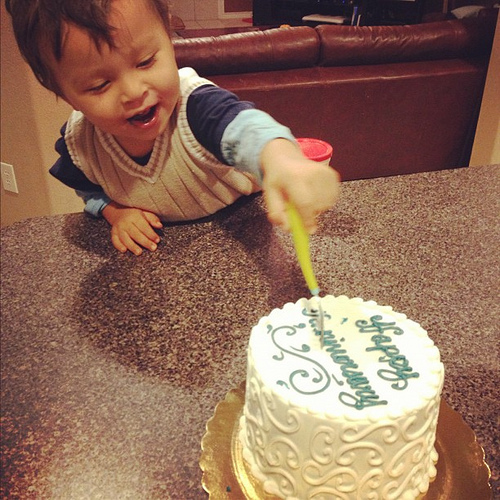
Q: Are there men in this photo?
A: No, there are no men.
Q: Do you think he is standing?
A: Yes, the boy is standing.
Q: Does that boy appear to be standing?
A: Yes, the boy is standing.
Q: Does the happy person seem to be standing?
A: Yes, the boy is standing.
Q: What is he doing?
A: The boy is standing.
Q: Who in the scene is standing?
A: The boy is standing.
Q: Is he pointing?
A: No, the boy is standing.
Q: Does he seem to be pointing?
A: No, the boy is standing.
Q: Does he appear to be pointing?
A: No, the boy is standing.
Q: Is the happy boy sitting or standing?
A: The boy is standing.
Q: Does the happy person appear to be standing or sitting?
A: The boy is standing.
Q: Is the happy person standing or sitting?
A: The boy is standing.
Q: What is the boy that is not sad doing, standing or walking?
A: The boy is standing.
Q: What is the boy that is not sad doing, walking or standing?
A: The boy is standing.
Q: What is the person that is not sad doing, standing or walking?
A: The boy is standing.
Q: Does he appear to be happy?
A: Yes, the boy is happy.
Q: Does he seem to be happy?
A: Yes, the boy is happy.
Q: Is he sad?
A: No, the boy is happy.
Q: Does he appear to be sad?
A: No, the boy is happy.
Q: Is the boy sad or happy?
A: The boy is happy.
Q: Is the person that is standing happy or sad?
A: The boy is happy.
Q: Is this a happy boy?
A: Yes, this is a happy boy.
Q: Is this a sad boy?
A: No, this is a happy boy.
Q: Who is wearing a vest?
A: The boy is wearing a vest.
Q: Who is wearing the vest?
A: The boy is wearing a vest.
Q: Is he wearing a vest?
A: Yes, the boy is wearing a vest.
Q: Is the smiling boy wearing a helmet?
A: No, the boy is wearing a vest.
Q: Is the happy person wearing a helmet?
A: No, the boy is wearing a vest.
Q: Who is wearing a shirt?
A: The boy is wearing a shirt.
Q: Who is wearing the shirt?
A: The boy is wearing a shirt.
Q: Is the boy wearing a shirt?
A: Yes, the boy is wearing a shirt.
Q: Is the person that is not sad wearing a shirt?
A: Yes, the boy is wearing a shirt.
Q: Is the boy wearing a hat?
A: No, the boy is wearing a shirt.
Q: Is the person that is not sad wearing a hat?
A: No, the boy is wearing a shirt.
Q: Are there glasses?
A: No, there are no glasses.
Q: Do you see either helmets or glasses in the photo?
A: No, there are no glasses or helmets.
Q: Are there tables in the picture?
A: Yes, there is a table.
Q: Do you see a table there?
A: Yes, there is a table.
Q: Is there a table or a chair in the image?
A: Yes, there is a table.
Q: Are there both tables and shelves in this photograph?
A: No, there is a table but no shelves.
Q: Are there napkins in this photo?
A: No, there are no napkins.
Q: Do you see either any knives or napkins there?
A: No, there are no napkins or knives.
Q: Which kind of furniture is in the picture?
A: The furniture is a table.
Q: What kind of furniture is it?
A: The piece of furniture is a table.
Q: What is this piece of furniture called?
A: This is a table.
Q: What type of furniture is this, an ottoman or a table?
A: This is a table.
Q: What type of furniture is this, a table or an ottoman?
A: This is a table.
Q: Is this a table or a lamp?
A: This is a table.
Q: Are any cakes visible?
A: Yes, there is a cake.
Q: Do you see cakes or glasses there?
A: Yes, there is a cake.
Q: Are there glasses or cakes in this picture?
A: Yes, there is a cake.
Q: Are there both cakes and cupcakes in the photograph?
A: No, there is a cake but no cupcakes.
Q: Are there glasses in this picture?
A: No, there are no glasses.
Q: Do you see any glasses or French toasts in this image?
A: No, there are no glasses or French toasts.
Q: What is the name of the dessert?
A: The dessert is a cake.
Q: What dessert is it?
A: The dessert is a cake.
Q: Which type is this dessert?
A: This is a cake.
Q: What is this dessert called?
A: This is a cake.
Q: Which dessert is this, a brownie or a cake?
A: This is a cake.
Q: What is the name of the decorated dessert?
A: The dessert is a cake.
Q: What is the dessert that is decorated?
A: The dessert is a cake.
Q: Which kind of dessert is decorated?
A: The dessert is a cake.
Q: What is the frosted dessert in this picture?
A: The dessert is a cake.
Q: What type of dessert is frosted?
A: The dessert is a cake.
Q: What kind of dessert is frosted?
A: The dessert is a cake.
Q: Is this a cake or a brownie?
A: This is a cake.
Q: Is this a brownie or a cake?
A: This is a cake.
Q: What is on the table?
A: The cake is on the table.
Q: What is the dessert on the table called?
A: The dessert is a cake.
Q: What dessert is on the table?
A: The dessert is a cake.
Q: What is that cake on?
A: The cake is on the table.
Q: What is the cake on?
A: The cake is on the table.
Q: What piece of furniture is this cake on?
A: The cake is on the table.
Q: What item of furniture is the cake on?
A: The cake is on the table.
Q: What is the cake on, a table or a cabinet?
A: The cake is on a table.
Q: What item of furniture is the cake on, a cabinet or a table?
A: The cake is on a table.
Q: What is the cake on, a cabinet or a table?
A: The cake is on a table.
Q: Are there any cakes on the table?
A: Yes, there is a cake on the table.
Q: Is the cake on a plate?
A: No, the cake is on the table.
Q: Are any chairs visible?
A: No, there are no chairs.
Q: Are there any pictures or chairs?
A: No, there are no chairs or pictures.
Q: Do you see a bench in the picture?
A: No, there are no benches.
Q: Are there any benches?
A: No, there are no benches.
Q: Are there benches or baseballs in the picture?
A: No, there are no benches or baseballs.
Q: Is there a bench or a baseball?
A: No, there are no benches or baseballs.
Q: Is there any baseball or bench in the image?
A: No, there are no benches or baseballs.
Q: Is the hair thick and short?
A: No, the hair is short but thin.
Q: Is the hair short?
A: Yes, the hair is short.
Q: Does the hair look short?
A: Yes, the hair is short.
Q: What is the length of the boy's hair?
A: The hair is short.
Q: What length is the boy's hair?
A: The hair is short.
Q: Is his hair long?
A: No, the hair is short.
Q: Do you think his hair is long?
A: No, the hair is short.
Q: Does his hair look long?
A: No, the hair is short.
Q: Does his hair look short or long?
A: The hair is short.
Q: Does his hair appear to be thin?
A: Yes, the hair is thin.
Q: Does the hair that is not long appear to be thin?
A: Yes, the hair is thin.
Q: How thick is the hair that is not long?
A: The hair is thin.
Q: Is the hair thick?
A: No, the hair is thin.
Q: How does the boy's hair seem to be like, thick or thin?
A: The hair is thin.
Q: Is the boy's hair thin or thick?
A: The hair is thin.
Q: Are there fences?
A: No, there are no fences.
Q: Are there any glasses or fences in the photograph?
A: No, there are no fences or glasses.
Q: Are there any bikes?
A: No, there are no bikes.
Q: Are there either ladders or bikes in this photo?
A: No, there are no bikes or ladders.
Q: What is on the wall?
A: The outlet is on the wall.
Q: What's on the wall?
A: The outlet is on the wall.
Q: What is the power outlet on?
A: The power outlet is on the wall.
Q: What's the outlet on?
A: The power outlet is on the wall.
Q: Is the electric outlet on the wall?
A: Yes, the electric outlet is on the wall.